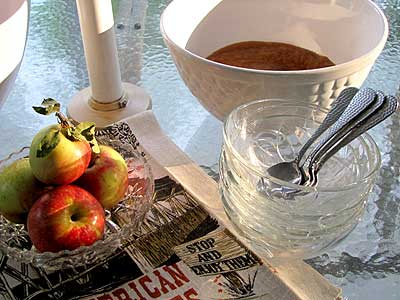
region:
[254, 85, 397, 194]
four teaspoons in glass bowl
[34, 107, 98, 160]
green leaves on an apple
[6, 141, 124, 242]
four apples in a bowl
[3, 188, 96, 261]
red and green apple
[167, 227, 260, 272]
stop and enjoy them sign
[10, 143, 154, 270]
apples with glass bowl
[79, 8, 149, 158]
white candle stick with gold base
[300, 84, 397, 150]
ends of four silver spoons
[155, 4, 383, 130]
white bowl with liquid in it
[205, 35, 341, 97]
brown liquid in a bowl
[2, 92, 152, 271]
apples in a small bowl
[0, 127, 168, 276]
the bowl is clear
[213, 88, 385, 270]
bowls are stacked on top of each other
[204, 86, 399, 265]
silver spoons are in the bowl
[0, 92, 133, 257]
the apples are red and green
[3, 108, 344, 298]
the bowl is on top of a newpaper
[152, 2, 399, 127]
a big white bowl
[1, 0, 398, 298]
the table is glass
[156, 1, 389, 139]
the white bowl has something brown in it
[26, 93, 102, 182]
one of the apples has leaves on it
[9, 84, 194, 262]
a bowl of apples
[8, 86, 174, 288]
a bowl of red and green apples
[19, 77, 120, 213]
an apple with leaves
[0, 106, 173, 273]
a clear bowl of apples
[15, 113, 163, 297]
a clear bowl of red and green apples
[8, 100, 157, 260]
freshly picked apples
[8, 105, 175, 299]
freshly picked apples in a bowl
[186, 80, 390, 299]
a stack of bowls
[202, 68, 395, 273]
a stack of clear bowls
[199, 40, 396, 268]
spoons in a bowl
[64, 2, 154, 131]
white metal pole wirth gold accents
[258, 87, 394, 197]
silver teaspoons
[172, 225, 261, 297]
sign on newspaper that says Stop and Drink Them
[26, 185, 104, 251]
red apple in a clear bowl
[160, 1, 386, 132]
white serving bowl with beans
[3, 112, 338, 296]
newspaper on the table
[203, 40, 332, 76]
brown beans in a white bowl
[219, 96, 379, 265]
stack of clear glass bowls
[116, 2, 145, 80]
reflection on table of white poles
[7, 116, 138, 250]
four apples in the glass bowl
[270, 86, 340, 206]
steel spoons with bowl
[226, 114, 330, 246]
glass bowls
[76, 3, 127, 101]
white colour steel post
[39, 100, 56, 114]
leaf of the apple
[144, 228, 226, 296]
newspaper and book kept in the table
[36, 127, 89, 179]
red with green colour apple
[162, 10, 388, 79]
a white colour ceramic bowl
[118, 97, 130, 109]
bolt of the steel post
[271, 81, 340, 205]
four silver spoon kept in a glass bowl